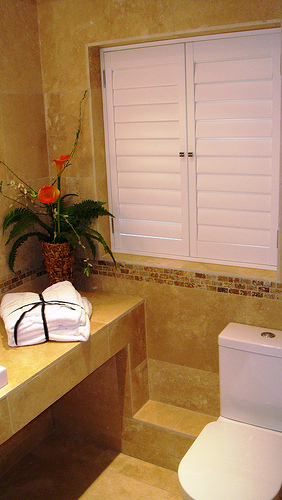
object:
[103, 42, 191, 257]
shutters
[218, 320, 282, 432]
tank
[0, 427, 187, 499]
floor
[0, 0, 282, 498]
bathroom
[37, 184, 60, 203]
flowers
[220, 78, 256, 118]
ground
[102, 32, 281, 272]
window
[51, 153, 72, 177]
flowers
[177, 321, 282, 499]
toilet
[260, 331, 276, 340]
button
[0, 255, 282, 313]
mosaic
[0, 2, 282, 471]
wall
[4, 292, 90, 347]
black ribbon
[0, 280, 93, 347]
towels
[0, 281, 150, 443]
table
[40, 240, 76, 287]
planter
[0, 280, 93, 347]
clothes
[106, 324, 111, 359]
grout line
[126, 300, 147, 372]
tile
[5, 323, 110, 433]
tile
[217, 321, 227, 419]
edge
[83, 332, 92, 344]
part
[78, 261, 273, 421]
side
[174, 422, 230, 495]
part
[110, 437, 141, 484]
tiles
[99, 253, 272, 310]
tiles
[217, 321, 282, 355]
top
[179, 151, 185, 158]
handles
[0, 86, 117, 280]
plant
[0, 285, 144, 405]
counter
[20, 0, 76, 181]
corner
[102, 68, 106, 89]
hinge